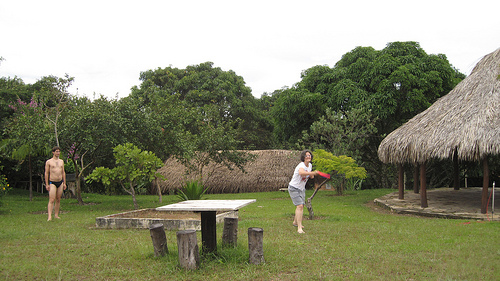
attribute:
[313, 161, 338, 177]
frisbee — red, throwing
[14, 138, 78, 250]
man — naked, nude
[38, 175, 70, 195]
speedo — black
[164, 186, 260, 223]
table — white, picnic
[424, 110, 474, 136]
hut — straw, grass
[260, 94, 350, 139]
tree — green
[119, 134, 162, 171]
grass — green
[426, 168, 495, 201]
wood — box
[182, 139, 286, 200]
roof — straw